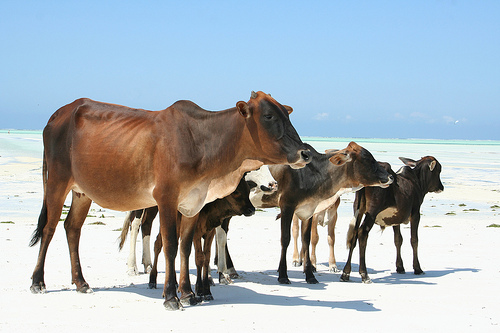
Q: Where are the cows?
A: On sand.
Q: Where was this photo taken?
A: Beach.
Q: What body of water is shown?
A: Ocean.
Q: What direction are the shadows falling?
A: Right.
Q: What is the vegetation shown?
A: Sea weed.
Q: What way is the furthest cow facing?
A: Towards ocean.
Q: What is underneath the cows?
A: Shadows.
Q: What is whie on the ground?
A: Snow.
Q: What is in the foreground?
A: Large cow in front of other cows.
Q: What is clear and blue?
A: The sky.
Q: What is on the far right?
A: A baby cow.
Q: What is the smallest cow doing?
A: Looking into the horizon.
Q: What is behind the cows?
A: Blue skies.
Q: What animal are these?
A: Cows.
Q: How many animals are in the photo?
A: Four.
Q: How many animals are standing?
A: Four.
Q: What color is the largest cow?
A: Brown.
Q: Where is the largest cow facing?
A: Right.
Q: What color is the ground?
A: White.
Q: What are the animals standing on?
A: Snow.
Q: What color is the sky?
A: Blue.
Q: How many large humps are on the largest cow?
A: One.